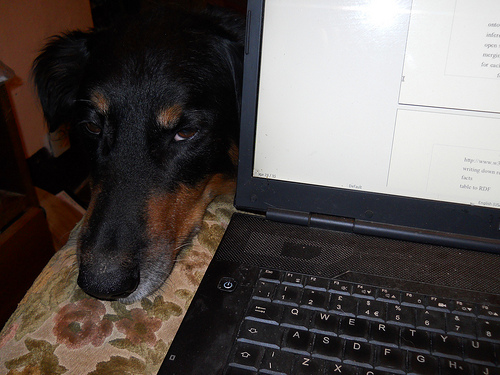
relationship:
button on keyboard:
[219, 279, 233, 294] [171, 219, 498, 373]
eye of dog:
[161, 102, 207, 159] [27, 9, 254, 336]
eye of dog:
[76, 106, 105, 138] [40, 8, 243, 304]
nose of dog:
[71, 265, 145, 297] [37, 69, 170, 289]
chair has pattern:
[1, 177, 235, 371] [14, 295, 139, 373]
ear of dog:
[26, 15, 109, 145] [40, 8, 243, 304]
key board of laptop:
[216, 254, 499, 364] [145, 3, 497, 368]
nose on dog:
[73, 264, 146, 296] [24, 0, 352, 364]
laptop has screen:
[160, 0, 500, 375] [253, 0, 498, 207]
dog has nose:
[31, 0, 244, 304] [53, 249, 181, 314]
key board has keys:
[187, 215, 491, 367] [276, 293, 425, 370]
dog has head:
[31, 0, 244, 304] [16, 28, 261, 283]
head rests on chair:
[16, 28, 261, 283] [1, 209, 208, 372]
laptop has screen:
[203, 17, 474, 364] [247, 7, 485, 202]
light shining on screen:
[251, 6, 499, 213] [261, 7, 493, 224]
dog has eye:
[20, 0, 266, 309] [170, 121, 202, 149]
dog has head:
[31, 0, 244, 304] [27, 7, 235, 310]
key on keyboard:
[299, 279, 337, 315] [235, 256, 497, 368]